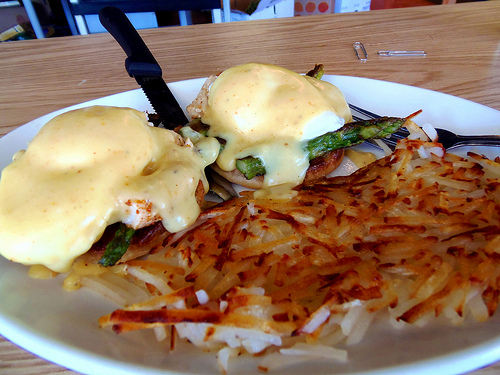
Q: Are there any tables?
A: Yes, there is a table.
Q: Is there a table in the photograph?
A: Yes, there is a table.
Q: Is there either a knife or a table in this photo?
A: Yes, there is a table.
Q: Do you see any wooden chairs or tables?
A: Yes, there is a wood table.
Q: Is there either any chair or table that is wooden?
A: Yes, the table is wooden.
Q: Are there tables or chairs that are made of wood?
A: Yes, the table is made of wood.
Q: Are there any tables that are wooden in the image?
A: Yes, there is a wood table.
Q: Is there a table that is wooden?
A: Yes, there is a table that is wooden.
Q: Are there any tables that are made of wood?
A: Yes, there is a table that is made of wood.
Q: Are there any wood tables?
A: Yes, there is a table that is made of wood.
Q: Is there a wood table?
A: Yes, there is a table that is made of wood.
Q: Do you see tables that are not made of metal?
A: Yes, there is a table that is made of wood.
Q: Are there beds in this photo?
A: No, there are no beds.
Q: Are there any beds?
A: No, there are no beds.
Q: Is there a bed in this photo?
A: No, there are no beds.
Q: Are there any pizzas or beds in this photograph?
A: No, there are no beds or pizzas.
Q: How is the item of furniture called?
A: The piece of furniture is a table.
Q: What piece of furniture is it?
A: The piece of furniture is a table.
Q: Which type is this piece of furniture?
A: This is a table.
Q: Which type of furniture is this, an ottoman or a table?
A: This is a table.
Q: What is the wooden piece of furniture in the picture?
A: The piece of furniture is a table.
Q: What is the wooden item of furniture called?
A: The piece of furniture is a table.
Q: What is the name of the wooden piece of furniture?
A: The piece of furniture is a table.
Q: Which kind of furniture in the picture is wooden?
A: The furniture is a table.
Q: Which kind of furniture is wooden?
A: The furniture is a table.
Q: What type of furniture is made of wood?
A: The furniture is a table.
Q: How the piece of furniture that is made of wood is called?
A: The piece of furniture is a table.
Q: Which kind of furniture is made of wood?
A: The furniture is a table.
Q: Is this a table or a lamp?
A: This is a table.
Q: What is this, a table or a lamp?
A: This is a table.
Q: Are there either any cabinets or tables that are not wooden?
A: No, there is a table but it is wooden.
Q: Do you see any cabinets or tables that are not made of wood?
A: No, there is a table but it is made of wood.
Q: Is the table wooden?
A: Yes, the table is wooden.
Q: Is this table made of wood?
A: Yes, the table is made of wood.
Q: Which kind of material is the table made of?
A: The table is made of wood.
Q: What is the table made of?
A: The table is made of wood.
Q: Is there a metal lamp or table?
A: No, there is a table but it is wooden.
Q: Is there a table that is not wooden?
A: No, there is a table but it is wooden.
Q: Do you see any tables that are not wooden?
A: No, there is a table but it is wooden.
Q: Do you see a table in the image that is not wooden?
A: No, there is a table but it is wooden.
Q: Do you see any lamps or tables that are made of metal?
A: No, there is a table but it is made of wood.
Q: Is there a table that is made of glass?
A: No, there is a table but it is made of wood.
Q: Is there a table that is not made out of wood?
A: No, there is a table but it is made of wood.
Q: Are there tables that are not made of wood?
A: No, there is a table but it is made of wood.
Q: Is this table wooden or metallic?
A: The table is wooden.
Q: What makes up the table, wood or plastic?
A: The table is made of wood.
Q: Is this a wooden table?
A: Yes, this is a wooden table.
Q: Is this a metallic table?
A: No, this is a wooden table.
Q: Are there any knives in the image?
A: Yes, there is a knife.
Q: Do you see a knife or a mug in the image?
A: Yes, there is a knife.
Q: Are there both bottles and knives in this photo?
A: No, there is a knife but no bottles.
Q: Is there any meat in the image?
A: No, there is no meat.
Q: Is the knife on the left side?
A: Yes, the knife is on the left of the image.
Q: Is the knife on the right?
A: No, the knife is on the left of the image.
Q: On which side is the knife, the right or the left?
A: The knife is on the left of the image.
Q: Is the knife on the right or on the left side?
A: The knife is on the left of the image.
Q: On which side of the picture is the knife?
A: The knife is on the left of the image.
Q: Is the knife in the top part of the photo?
A: Yes, the knife is in the top of the image.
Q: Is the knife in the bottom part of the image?
A: No, the knife is in the top of the image.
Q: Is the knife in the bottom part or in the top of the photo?
A: The knife is in the top of the image.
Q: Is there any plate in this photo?
A: Yes, there is a plate.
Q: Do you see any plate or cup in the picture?
A: Yes, there is a plate.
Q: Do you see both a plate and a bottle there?
A: No, there is a plate but no bottles.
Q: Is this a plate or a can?
A: This is a plate.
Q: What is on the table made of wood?
A: The plate is on the table.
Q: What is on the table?
A: The plate is on the table.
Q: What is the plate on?
A: The plate is on the table.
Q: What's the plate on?
A: The plate is on the table.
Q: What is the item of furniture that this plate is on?
A: The piece of furniture is a table.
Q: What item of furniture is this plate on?
A: The plate is on the table.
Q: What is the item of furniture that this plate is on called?
A: The piece of furniture is a table.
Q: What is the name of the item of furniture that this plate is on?
A: The piece of furniture is a table.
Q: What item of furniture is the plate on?
A: The plate is on the table.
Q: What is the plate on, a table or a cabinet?
A: The plate is on a table.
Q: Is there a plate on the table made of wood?
A: Yes, there is a plate on the table.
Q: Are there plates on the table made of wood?
A: Yes, there is a plate on the table.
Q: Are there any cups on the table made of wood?
A: No, there is a plate on the table.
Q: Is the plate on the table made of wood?
A: Yes, the plate is on the table.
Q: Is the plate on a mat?
A: No, the plate is on the table.